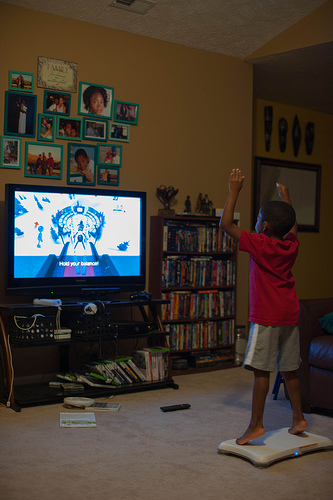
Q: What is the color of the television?
A: Black.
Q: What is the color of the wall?
A: Yellow.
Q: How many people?
A: 1.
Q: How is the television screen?
A: On.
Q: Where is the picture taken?
A: In a living room.